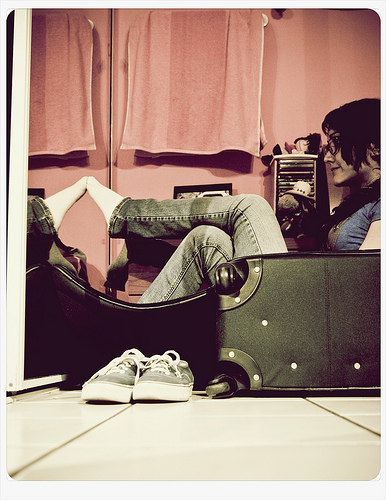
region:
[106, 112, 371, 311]
woman sitting in suitcase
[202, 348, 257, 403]
wheel on bottom of suitcase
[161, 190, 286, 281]
crossed legs in jeans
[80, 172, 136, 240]
white sock on foot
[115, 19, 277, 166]
towel hanging on wall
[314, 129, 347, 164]
glasses on girl's face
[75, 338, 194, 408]
pair of sneakers on floor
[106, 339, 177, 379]
white laces on sneakers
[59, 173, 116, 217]
refelction of foot in mirror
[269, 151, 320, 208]
rack with compact discs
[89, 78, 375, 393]
woman sitting by a mirror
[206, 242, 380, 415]
black luggage on the ground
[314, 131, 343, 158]
eyeglasses on a woman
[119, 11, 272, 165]
towel hanging from a wall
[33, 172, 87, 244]
reflection of foot in mirror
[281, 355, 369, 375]
silver rivets on luggage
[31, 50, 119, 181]
mirror on the wall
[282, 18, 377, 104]
pink wall behind woman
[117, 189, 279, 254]
jeans on a woman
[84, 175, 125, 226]
White sock on a woman's foot.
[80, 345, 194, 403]
A woman's sneakers on the ground.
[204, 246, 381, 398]
The bottom side of a large black suitcase.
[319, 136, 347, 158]
Glasses on the face of a woman.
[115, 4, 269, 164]
A towel hanging on a rack above a woman.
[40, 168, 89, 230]
Reflection of a white sock in the mirror.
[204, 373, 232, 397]
Wheel of a suitcase almost touching the floor.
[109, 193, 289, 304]
Jeans on a woman sitting on the floor.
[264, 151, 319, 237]
A cd tower holding many cd's.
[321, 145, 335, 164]
Nose on the front of a woman's face.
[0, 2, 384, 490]
vintage filter photo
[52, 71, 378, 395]
girl sitting in black suitcase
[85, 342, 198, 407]
white and grey shoes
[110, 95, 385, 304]
girl wearing blue jeans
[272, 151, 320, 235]
assorted DVDs on shelf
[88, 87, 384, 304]
girl wearing black glasses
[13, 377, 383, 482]
floor with white tiles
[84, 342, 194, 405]
grey and white shoes with laces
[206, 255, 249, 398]
black wheels on luggage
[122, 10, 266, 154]
pink towel hanging on wall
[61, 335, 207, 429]
blue and white shoea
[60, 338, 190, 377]
white shoe strings on shoes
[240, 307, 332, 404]
silver buttons on black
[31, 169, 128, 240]
two socks and jeans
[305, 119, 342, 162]
a pair of black glasses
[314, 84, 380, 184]
a woman with short hair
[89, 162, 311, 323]
a woman in jeans and socks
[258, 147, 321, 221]
cs'a on a tower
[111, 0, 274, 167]
pink towel on window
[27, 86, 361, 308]
person reading a book